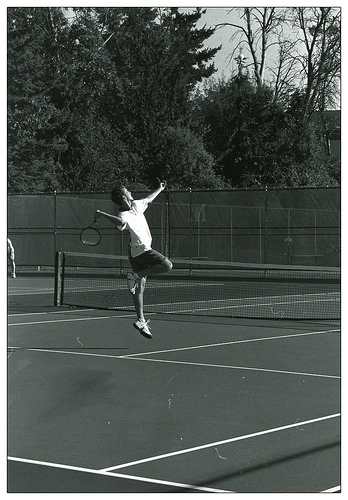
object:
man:
[94, 183, 173, 339]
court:
[9, 260, 343, 489]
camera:
[2, 12, 342, 495]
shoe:
[127, 271, 141, 295]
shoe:
[133, 318, 153, 338]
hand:
[93, 208, 102, 219]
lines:
[9, 291, 342, 316]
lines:
[123, 327, 339, 354]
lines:
[8, 455, 94, 481]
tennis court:
[177, 321, 252, 375]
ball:
[161, 180, 166, 188]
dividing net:
[53, 249, 341, 324]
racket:
[80, 215, 101, 246]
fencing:
[185, 191, 343, 275]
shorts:
[128, 246, 167, 273]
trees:
[6, 6, 340, 191]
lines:
[120, 355, 339, 380]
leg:
[139, 250, 172, 285]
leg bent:
[147, 255, 172, 276]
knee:
[158, 257, 172, 273]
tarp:
[203, 173, 312, 252]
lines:
[71, 413, 340, 474]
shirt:
[115, 198, 152, 259]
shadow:
[5, 345, 128, 353]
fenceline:
[8, 193, 344, 269]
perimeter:
[7, 265, 339, 277]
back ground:
[41, 180, 343, 264]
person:
[7, 234, 16, 279]